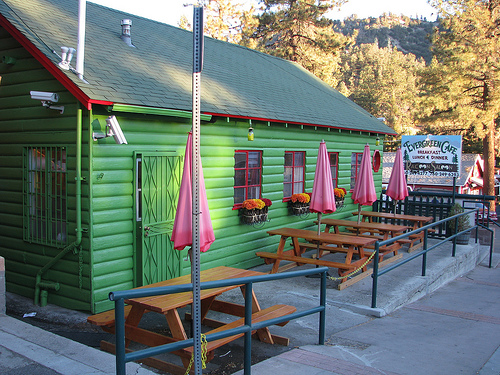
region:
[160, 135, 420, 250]
pink umbrellas at the tables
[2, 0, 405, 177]
a black roof on a green house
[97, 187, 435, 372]
wooden tables outside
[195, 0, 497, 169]
trees outside of the restaurant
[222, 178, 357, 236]
orange and red flowers in the windows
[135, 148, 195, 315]
a green door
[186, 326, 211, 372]
a yellow chain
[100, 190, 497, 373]
green fence around the tables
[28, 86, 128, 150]
cameras on the corner of the house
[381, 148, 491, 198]
a red house behind the sign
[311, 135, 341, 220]
the umbrella is pink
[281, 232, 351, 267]
the pinic table is brown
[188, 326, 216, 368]
the rope is yellow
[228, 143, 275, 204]
the window frame is red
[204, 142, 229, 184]
the building is neon green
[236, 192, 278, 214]
the flowers are orange yellow and red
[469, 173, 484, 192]
the building is red and white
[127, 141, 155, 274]
the door is cracked open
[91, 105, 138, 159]
the camera is pointing towards the door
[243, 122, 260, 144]
the feeder is yellow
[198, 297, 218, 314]
edge of a chair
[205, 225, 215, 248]
part of an umbrella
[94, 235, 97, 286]
side of a house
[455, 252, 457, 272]
edge of a path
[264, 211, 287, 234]
part of a flower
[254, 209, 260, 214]
edge of a flower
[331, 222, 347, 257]
part of a board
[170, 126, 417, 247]
pink umbrellas on the tables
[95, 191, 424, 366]
wooden picnic tables outside the house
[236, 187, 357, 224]
flower boxes outside the windows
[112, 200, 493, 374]
blue railing around the tables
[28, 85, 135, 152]
cameras outside of the restaurant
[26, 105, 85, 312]
green pipe on the side of the building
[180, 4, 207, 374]
a thin metal pole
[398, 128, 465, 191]
sign outside the green house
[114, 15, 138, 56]
chimney on the roof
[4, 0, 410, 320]
green building with a gray roof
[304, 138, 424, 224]
row of three pink umbrellas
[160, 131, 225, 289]
umbrella is closed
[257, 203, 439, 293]
row of three picnic tables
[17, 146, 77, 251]
green bars on the window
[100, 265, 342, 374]
small blue railing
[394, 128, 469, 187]
sign for the cafe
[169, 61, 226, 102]
sunlight shining on the roof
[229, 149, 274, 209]
red window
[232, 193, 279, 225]
plants in a planter under the window